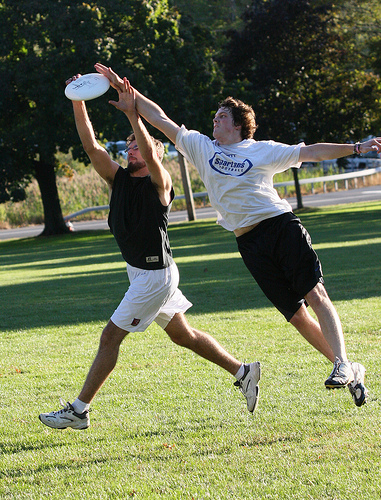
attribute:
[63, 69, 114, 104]
frisbee — round, white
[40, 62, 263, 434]
man — jumping, trying, mid jump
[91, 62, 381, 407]
man — jumping, trying, mid jump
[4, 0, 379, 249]
trees — tall, leafy, green, large, full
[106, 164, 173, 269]
t-shirt — black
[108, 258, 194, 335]
shorts — white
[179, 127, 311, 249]
t-shirt — white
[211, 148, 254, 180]
logo — blue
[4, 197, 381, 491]
grass — green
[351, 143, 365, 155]
wrist — man's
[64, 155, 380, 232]
guard rail — silver, metal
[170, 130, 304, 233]
shirt — white, black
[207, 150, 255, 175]
letters — blue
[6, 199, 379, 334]
shade — cast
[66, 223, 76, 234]
hydrant — red, white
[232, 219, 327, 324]
shorts — black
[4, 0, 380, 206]
leaves — green, tree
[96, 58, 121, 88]
hand — stretched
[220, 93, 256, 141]
hair — brown